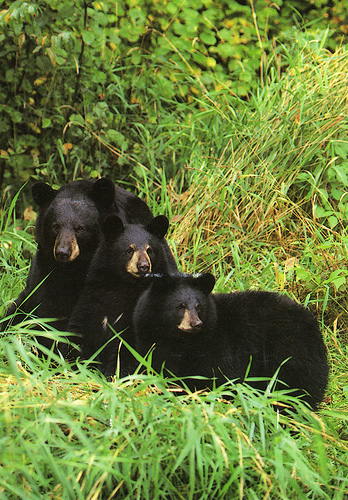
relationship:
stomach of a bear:
[76, 278, 148, 369] [75, 206, 184, 377]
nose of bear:
[42, 238, 79, 266] [19, 173, 132, 351]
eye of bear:
[48, 209, 92, 242] [19, 173, 132, 351]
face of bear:
[114, 214, 173, 283] [75, 206, 184, 377]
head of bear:
[100, 203, 184, 291] [75, 206, 184, 377]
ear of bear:
[96, 206, 188, 246] [75, 206, 184, 377]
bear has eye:
[75, 206, 184, 377] [48, 209, 92, 242]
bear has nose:
[75, 206, 184, 377] [42, 238, 79, 266]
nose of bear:
[122, 254, 174, 291] [75, 206, 184, 377]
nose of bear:
[177, 309, 225, 339] [115, 247, 346, 421]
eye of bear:
[162, 291, 231, 323] [115, 247, 346, 421]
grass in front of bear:
[45, 363, 208, 499] [75, 206, 184, 377]